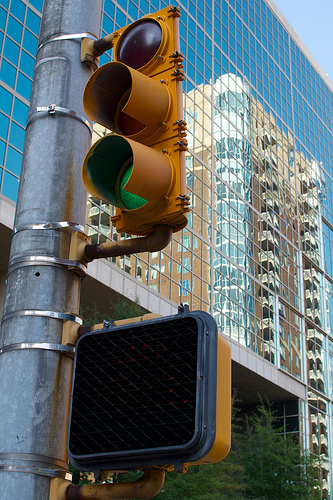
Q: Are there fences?
A: No, there are no fences.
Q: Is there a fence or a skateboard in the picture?
A: No, there are no fences or skateboards.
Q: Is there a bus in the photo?
A: No, there are no buses.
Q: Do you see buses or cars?
A: No, there are no buses or cars.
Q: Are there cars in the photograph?
A: No, there are no cars.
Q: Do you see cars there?
A: No, there are no cars.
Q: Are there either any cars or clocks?
A: No, there are no cars or clocks.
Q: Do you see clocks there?
A: No, there are no clocks.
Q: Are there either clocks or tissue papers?
A: No, there are no clocks or tissue papers.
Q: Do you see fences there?
A: No, there are no fences.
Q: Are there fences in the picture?
A: No, there are no fences.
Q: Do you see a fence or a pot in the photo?
A: No, there are no fences or pots.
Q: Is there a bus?
A: No, there are no buses.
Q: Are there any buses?
A: No, there are no buses.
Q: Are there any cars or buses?
A: No, there are no buses or cars.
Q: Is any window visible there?
A: Yes, there are windows.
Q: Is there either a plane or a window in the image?
A: Yes, there are windows.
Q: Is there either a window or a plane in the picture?
A: Yes, there are windows.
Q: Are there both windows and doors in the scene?
A: No, there are windows but no doors.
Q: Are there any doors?
A: No, there are no doors.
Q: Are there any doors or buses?
A: No, there are no doors or buses.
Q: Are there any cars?
A: No, there are no cars.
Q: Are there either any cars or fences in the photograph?
A: No, there are no cars or fences.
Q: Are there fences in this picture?
A: No, there are no fences.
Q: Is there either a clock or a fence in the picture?
A: No, there are no fences or clocks.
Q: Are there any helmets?
A: No, there are no helmets.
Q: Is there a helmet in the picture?
A: No, there are no helmets.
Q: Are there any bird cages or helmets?
A: No, there are no helmets or bird cages.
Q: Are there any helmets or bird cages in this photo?
A: No, there are no helmets or bird cages.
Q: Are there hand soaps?
A: No, there are no hand soaps.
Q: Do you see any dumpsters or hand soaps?
A: No, there are no hand soaps or dumpsters.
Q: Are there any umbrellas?
A: No, there are no umbrellas.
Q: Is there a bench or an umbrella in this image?
A: No, there are no umbrellas or benches.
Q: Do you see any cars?
A: No, there are no cars.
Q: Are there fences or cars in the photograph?
A: No, there are no cars or fences.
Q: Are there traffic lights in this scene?
A: Yes, there is a traffic light.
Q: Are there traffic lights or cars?
A: Yes, there is a traffic light.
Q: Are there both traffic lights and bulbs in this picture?
A: No, there is a traffic light but no light bulbs.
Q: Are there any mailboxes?
A: No, there are no mailboxes.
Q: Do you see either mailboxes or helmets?
A: No, there are no mailboxes or helmets.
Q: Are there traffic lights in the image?
A: Yes, there is a traffic light.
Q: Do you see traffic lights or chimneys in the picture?
A: Yes, there is a traffic light.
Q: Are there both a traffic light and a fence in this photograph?
A: No, there is a traffic light but no fences.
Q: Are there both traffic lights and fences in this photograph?
A: No, there is a traffic light but no fences.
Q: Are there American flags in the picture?
A: No, there are no American flags.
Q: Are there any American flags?
A: No, there are no American flags.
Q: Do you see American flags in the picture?
A: No, there are no American flags.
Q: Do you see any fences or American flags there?
A: No, there are no American flags or fences.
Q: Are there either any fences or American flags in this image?
A: No, there are no American flags or fences.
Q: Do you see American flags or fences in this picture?
A: No, there are no American flags or fences.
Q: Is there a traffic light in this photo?
A: Yes, there is a traffic light.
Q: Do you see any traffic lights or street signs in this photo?
A: Yes, there is a traffic light.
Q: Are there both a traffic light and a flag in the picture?
A: No, there is a traffic light but no flags.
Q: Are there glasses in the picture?
A: No, there are no glasses.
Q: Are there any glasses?
A: No, there are no glasses.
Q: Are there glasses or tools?
A: No, there are no glasses or tools.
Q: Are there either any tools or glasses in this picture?
A: No, there are no glasses or tools.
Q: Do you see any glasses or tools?
A: No, there are no glasses or tools.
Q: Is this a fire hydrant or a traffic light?
A: This is a traffic light.